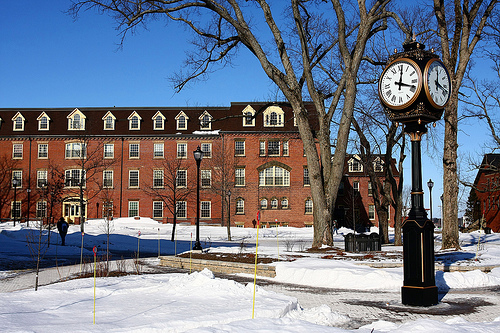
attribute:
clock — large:
[378, 40, 450, 127]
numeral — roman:
[395, 94, 403, 103]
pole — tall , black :
[184, 144, 214, 251]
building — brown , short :
[1, 94, 333, 226]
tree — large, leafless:
[66, 0, 403, 250]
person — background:
[38, 203, 90, 263]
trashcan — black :
[342, 233, 353, 250]